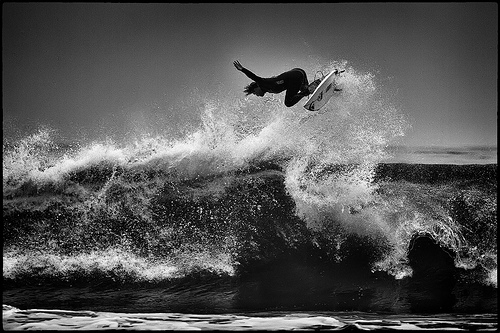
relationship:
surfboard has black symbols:
[302, 62, 352, 114] [318, 84, 333, 104]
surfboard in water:
[303, 67, 343, 112] [0, 60, 496, 330]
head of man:
[238, 46, 274, 116] [227, 58, 322, 108]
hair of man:
[240, 78, 267, 95] [221, 48, 321, 109]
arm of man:
[231, 58, 269, 84] [228, 64, 355, 120]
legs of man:
[282, 67, 326, 108] [226, 55, 323, 110]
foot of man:
[304, 76, 323, 95] [243, 53, 347, 128]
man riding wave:
[226, 55, 323, 110] [3, 138, 499, 328]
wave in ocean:
[7, 137, 493, 308] [0, 164, 498, 330]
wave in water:
[3, 140, 380, 282] [268, 279, 310, 294]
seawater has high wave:
[34, 157, 497, 330] [273, 126, 488, 264]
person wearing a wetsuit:
[232, 57, 319, 108] [239, 62, 312, 110]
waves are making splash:
[58, 135, 203, 180] [323, 71, 395, 166]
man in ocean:
[234, 63, 326, 108] [2, 146, 497, 331]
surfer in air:
[212, 38, 402, 143] [32, 15, 480, 109]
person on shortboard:
[228, 55, 325, 112] [302, 64, 346, 109]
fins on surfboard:
[322, 62, 382, 122] [299, 61, 347, 113]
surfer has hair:
[230, 58, 319, 107] [241, 85, 254, 96]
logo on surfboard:
[295, 91, 372, 125] [305, 77, 350, 113]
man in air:
[232, 56, 322, 106] [53, 24, 373, 103]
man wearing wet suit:
[232, 61, 323, 106] [243, 67, 307, 107]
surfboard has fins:
[287, 49, 431, 113] [301, 62, 346, 114]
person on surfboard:
[222, 48, 376, 132] [303, 64, 345, 113]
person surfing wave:
[230, 56, 324, 106] [7, 137, 493, 308]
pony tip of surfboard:
[298, 96, 313, 111] [313, 78, 330, 100]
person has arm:
[229, 54, 313, 105] [229, 59, 268, 80]